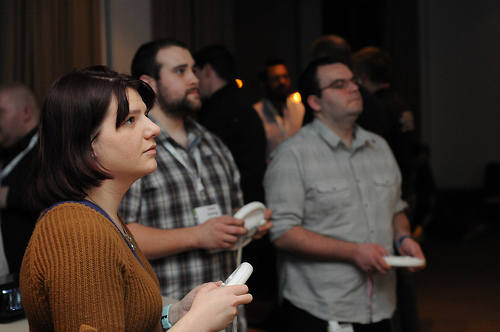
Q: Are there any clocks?
A: No, there are no clocks.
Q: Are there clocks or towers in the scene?
A: No, there are no clocks or towers.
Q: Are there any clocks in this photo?
A: No, there are no clocks.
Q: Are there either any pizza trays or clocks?
A: No, there are no clocks or pizza trays.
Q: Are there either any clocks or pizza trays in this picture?
A: No, there are no clocks or pizza trays.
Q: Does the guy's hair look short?
A: Yes, the hair is short.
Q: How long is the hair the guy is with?
A: The hair is short.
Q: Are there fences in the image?
A: No, there are no fences.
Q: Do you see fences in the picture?
A: No, there are no fences.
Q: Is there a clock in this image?
A: No, there are no clocks.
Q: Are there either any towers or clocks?
A: No, there are no clocks or towers.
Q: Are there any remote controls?
A: Yes, there is a remote control.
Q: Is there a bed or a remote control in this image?
A: Yes, there is a remote control.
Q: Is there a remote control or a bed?
A: Yes, there is a remote control.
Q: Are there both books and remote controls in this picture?
A: No, there is a remote control but no books.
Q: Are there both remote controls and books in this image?
A: No, there is a remote control but no books.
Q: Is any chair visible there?
A: No, there are no chairs.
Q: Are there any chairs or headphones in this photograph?
A: No, there are no chairs or headphones.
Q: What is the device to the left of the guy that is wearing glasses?
A: The device is a remote control.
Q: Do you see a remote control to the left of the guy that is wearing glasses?
A: Yes, there is a remote control to the left of the guy.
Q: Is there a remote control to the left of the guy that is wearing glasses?
A: Yes, there is a remote control to the left of the guy.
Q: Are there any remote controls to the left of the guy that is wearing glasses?
A: Yes, there is a remote control to the left of the guy.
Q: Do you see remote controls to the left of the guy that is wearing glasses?
A: Yes, there is a remote control to the left of the guy.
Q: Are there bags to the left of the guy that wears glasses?
A: No, there is a remote control to the left of the guy.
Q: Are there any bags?
A: No, there are no bags.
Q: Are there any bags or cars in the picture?
A: No, there are no bags or cars.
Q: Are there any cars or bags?
A: No, there are no bags or cars.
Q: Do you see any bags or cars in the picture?
A: No, there are no bags or cars.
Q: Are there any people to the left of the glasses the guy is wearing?
A: Yes, there are people to the left of the glasses.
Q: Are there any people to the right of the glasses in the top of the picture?
A: No, the people are to the left of the glasses.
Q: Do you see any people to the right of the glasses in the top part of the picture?
A: No, the people are to the left of the glasses.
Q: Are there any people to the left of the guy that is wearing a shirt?
A: Yes, there are people to the left of the guy.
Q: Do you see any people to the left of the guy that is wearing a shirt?
A: Yes, there are people to the left of the guy.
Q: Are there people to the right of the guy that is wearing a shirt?
A: No, the people are to the left of the guy.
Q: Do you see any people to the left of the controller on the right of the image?
A: Yes, there are people to the left of the controller.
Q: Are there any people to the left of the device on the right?
A: Yes, there are people to the left of the controller.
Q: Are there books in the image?
A: No, there are no books.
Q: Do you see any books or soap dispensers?
A: No, there are no books or soap dispensers.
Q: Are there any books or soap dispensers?
A: No, there are no books or soap dispensers.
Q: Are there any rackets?
A: No, there are no rackets.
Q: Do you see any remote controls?
A: Yes, there is a remote control.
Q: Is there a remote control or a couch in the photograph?
A: Yes, there is a remote control.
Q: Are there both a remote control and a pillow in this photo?
A: No, there is a remote control but no pillows.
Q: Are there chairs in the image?
A: No, there are no chairs.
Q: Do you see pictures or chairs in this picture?
A: No, there are no chairs or pictures.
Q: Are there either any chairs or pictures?
A: No, there are no chairs or pictures.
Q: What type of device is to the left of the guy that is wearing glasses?
A: The device is a remote control.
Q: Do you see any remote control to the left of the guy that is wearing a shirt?
A: Yes, there is a remote control to the left of the guy.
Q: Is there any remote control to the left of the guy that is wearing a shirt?
A: Yes, there is a remote control to the left of the guy.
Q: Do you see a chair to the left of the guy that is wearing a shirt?
A: No, there is a remote control to the left of the guy.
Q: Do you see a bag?
A: No, there are no bags.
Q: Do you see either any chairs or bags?
A: No, there are no bags or chairs.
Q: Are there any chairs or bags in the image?
A: No, there are no bags or chairs.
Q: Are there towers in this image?
A: No, there are no towers.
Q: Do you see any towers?
A: No, there are no towers.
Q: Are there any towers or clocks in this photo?
A: No, there are no towers or clocks.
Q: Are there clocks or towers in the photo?
A: No, there are no towers or clocks.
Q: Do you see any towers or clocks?
A: No, there are no towers or clocks.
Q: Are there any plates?
A: No, there are no plates.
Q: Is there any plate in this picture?
A: No, there are no plates.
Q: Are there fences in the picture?
A: No, there are no fences.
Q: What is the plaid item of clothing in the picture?
A: The clothing item is a shirt.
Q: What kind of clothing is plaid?
A: The clothing is a shirt.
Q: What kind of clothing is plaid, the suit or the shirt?
A: The shirt is plaid.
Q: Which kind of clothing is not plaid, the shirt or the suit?
A: The suit is not plaid.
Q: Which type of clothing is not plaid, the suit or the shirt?
A: The suit is not plaid.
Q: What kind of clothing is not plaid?
A: The clothing is a suit.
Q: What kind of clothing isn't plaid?
A: The clothing is a suit.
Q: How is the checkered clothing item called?
A: The clothing item is a shirt.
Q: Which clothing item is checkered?
A: The clothing item is a shirt.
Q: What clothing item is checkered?
A: The clothing item is a shirt.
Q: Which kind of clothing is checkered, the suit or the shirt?
A: The shirt is checkered.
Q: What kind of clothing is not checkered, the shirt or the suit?
A: The suit is not checkered.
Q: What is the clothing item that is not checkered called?
A: The clothing item is a suit.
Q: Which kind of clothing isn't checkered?
A: The clothing is a suit.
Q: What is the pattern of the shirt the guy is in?
A: The shirt is checkered.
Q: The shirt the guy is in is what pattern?
A: The shirt is checkered.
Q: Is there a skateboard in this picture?
A: No, there are no skateboards.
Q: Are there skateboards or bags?
A: No, there are no skateboards or bags.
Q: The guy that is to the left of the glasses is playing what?
A: The guy is playing a video game.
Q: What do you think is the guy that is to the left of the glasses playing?
A: The guy is playing a video game.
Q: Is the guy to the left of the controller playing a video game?
A: Yes, the guy is playing a video game.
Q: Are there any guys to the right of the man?
A: Yes, there is a guy to the right of the man.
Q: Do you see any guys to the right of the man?
A: Yes, there is a guy to the right of the man.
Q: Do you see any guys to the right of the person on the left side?
A: Yes, there is a guy to the right of the man.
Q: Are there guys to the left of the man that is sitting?
A: No, the guy is to the right of the man.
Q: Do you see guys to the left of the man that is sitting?
A: No, the guy is to the right of the man.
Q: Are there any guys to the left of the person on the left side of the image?
A: No, the guy is to the right of the man.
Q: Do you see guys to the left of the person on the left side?
A: No, the guy is to the right of the man.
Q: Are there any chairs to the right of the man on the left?
A: No, there is a guy to the right of the man.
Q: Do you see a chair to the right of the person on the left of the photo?
A: No, there is a guy to the right of the man.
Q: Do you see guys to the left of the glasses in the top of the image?
A: Yes, there is a guy to the left of the glasses.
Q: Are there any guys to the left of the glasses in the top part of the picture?
A: Yes, there is a guy to the left of the glasses.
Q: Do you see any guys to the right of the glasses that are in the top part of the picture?
A: No, the guy is to the left of the glasses.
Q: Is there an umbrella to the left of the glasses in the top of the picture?
A: No, there is a guy to the left of the glasses.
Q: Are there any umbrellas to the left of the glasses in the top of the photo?
A: No, there is a guy to the left of the glasses.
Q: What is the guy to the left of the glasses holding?
A: The guy is holding the remote.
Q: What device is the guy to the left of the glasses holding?
A: The guy is holding the remote control.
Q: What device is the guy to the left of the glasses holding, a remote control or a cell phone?
A: The guy is holding a remote control.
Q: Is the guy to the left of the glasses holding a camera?
A: No, the guy is holding the remote.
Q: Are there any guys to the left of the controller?
A: Yes, there is a guy to the left of the controller.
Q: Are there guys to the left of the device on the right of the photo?
A: Yes, there is a guy to the left of the controller.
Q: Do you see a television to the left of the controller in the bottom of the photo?
A: No, there is a guy to the left of the controller.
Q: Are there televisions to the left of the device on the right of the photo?
A: No, there is a guy to the left of the controller.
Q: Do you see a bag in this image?
A: No, there are no bags.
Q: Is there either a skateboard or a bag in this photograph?
A: No, there are no bags or skateboards.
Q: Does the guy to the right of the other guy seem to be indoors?
A: Yes, the guy is indoors.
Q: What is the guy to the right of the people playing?
A: The guy is playing a video game.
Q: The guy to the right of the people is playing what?
A: The guy is playing a video game.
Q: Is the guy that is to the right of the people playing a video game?
A: Yes, the guy is playing a video game.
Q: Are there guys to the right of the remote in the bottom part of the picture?
A: Yes, there is a guy to the right of the remote.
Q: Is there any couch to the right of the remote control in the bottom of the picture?
A: No, there is a guy to the right of the remote.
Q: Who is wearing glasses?
A: The guy is wearing glasses.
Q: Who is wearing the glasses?
A: The guy is wearing glasses.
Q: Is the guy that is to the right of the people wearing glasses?
A: Yes, the guy is wearing glasses.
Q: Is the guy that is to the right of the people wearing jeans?
A: No, the guy is wearing glasses.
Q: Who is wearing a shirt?
A: The guy is wearing a shirt.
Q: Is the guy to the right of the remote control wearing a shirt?
A: Yes, the guy is wearing a shirt.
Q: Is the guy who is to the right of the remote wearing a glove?
A: No, the guy is wearing a shirt.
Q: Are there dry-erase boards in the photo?
A: No, there are no dry-erase boards.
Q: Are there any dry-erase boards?
A: No, there are no dry-erase boards.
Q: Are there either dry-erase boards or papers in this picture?
A: No, there are no dry-erase boards or papers.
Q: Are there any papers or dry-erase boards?
A: No, there are no dry-erase boards or papers.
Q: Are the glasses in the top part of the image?
A: Yes, the glasses are in the top of the image.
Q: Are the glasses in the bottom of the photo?
A: No, the glasses are in the top of the image.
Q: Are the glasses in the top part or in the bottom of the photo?
A: The glasses are in the top of the image.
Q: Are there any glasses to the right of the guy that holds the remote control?
A: Yes, there are glasses to the right of the guy.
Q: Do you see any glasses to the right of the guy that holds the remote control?
A: Yes, there are glasses to the right of the guy.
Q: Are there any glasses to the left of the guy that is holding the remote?
A: No, the glasses are to the right of the guy.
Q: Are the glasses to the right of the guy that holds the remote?
A: Yes, the glasses are to the right of the guy.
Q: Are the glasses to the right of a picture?
A: No, the glasses are to the right of the guy.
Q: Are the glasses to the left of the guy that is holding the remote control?
A: No, the glasses are to the right of the guy.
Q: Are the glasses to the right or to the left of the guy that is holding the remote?
A: The glasses are to the right of the guy.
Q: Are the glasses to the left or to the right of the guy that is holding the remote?
A: The glasses are to the right of the guy.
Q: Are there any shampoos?
A: No, there are no shampoos.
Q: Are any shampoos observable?
A: No, there are no shampoos.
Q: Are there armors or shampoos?
A: No, there are no shampoos or armors.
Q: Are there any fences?
A: No, there are no fences.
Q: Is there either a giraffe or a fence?
A: No, there are no fences or giraffes.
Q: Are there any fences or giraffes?
A: No, there are no fences or giraffes.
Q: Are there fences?
A: No, there are no fences.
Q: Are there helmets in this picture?
A: No, there are no helmets.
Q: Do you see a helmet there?
A: No, there are no helmets.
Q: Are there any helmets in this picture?
A: No, there are no helmets.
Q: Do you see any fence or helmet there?
A: No, there are no helmets or fences.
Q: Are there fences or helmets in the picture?
A: No, there are no helmets or fences.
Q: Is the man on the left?
A: Yes, the man is on the left of the image.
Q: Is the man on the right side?
A: No, the man is on the left of the image.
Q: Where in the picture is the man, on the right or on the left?
A: The man is on the left of the image.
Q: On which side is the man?
A: The man is on the left of the image.